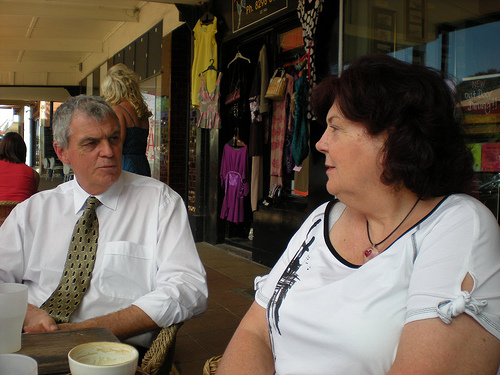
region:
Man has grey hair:
[49, 98, 79, 130]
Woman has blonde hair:
[101, 67, 141, 97]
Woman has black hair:
[364, 72, 436, 129]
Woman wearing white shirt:
[325, 281, 390, 366]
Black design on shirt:
[263, 237, 308, 322]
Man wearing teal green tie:
[59, 197, 105, 301]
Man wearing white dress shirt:
[32, 204, 64, 251]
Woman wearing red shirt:
[1, 159, 36, 199]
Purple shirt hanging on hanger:
[216, 136, 252, 237]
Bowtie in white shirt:
[431, 268, 490, 340]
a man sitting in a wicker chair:
[0, 93, 205, 366]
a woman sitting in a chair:
[211, 58, 498, 372]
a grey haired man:
[47, 93, 132, 198]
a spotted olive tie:
[36, 196, 103, 327]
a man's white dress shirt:
[0, 169, 212, 346]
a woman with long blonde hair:
[93, 59, 153, 173]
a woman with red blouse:
[0, 128, 41, 203]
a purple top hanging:
[213, 131, 248, 223]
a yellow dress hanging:
[185, 14, 219, 109]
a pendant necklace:
[356, 192, 416, 264]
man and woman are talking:
[17, 14, 492, 232]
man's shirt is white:
[10, 174, 205, 372]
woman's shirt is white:
[258, 180, 479, 367]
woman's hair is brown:
[304, 37, 495, 219]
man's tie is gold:
[27, 190, 121, 342]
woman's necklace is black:
[301, 184, 451, 304]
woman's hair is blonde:
[84, 60, 158, 128]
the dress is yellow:
[172, 8, 239, 116]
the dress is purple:
[200, 118, 251, 236]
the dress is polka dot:
[287, 4, 328, 104]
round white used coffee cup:
[66, 339, 142, 374]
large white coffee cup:
[0, 280, 30, 353]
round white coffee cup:
[1, 349, 43, 374]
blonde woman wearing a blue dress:
[88, 60, 155, 218]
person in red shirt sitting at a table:
[0, 125, 42, 228]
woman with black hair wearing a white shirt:
[186, 52, 498, 374]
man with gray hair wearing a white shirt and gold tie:
[1, 91, 211, 372]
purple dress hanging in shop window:
[209, 123, 252, 232]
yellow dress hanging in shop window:
[184, 6, 223, 117]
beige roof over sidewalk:
[0, 0, 202, 112]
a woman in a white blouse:
[214, 56, 498, 373]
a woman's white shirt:
[252, 198, 497, 372]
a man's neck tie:
[41, 191, 101, 319]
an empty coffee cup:
[64, 341, 139, 373]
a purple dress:
[218, 135, 248, 223]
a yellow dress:
[192, 18, 220, 110]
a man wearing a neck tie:
[0, 95, 208, 327]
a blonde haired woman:
[100, 62, 152, 176]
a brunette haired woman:
[212, 55, 497, 373]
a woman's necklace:
[364, 195, 421, 257]